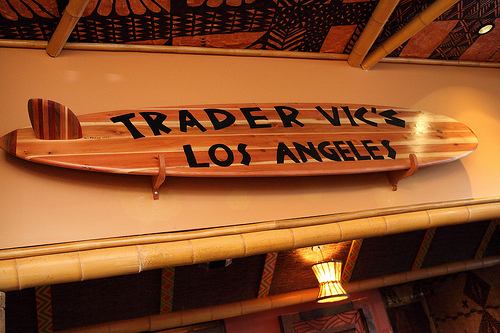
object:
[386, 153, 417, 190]
bracket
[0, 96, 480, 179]
surfboard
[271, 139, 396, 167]
words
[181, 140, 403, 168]
los angeles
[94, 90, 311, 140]
trader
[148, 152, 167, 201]
wooden hanger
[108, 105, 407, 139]
black text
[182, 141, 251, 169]
word